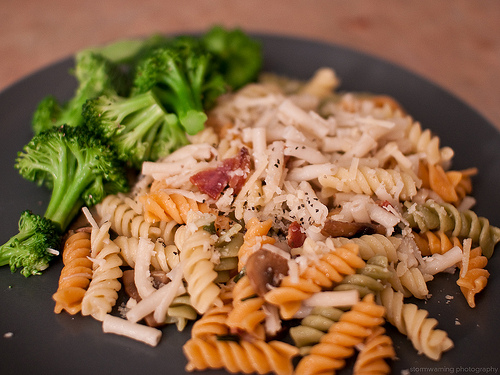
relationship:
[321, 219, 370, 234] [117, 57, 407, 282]
bacon in salad